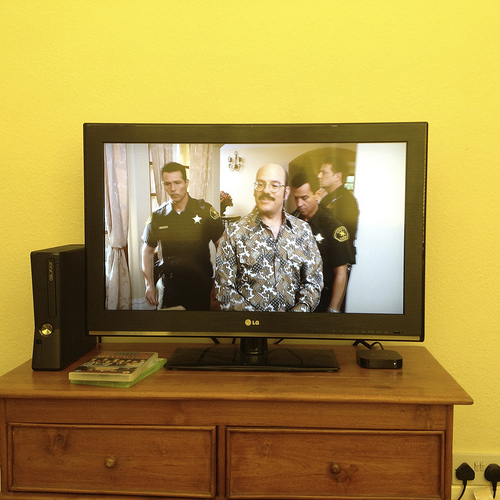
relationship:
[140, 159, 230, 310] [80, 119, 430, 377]
officer on face of television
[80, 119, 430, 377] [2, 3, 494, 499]
television in front of wall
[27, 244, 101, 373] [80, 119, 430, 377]
xbox next to television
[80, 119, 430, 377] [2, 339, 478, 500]
television on top of dresser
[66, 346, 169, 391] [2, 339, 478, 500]
game on top of dresser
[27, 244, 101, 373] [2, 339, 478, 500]
xbox on top of dresser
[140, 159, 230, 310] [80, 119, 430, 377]
officer on screen of television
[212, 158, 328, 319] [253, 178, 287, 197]
man wearing spectacles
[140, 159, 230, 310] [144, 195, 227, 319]
officer inside of uniform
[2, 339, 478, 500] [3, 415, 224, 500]
dresser has drawer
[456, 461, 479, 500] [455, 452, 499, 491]
plug on face of outlet